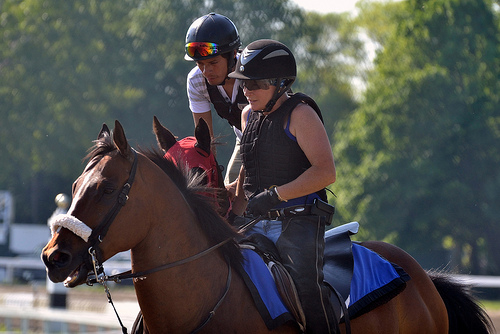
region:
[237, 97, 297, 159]
this is a woman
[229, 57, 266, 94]
this is a helmet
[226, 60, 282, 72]
the helmet is round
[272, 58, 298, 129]
the helmet is black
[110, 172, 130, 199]
this is a horse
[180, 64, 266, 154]
this is a man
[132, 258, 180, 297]
this is a strap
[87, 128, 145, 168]
this is an ear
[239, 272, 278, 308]
this is a blanket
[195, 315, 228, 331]
this is made of leather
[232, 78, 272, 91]
a pair of shades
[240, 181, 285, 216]
a pair of black gloves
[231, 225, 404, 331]
a blue saddle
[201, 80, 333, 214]
a black vest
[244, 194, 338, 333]
a pair of pants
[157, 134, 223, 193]
red mask on horse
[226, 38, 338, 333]
a lady jockey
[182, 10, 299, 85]
two helmets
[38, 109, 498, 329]
a brown horse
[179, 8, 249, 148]
a male rider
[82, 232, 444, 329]
the horse is brown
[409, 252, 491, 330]
the tail is black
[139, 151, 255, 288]
the mane is black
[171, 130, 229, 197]
the mask is red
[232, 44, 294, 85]
logo on the helmet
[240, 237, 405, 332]
blue blanket on horse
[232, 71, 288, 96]
the glasses on face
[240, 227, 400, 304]
saddle is on blanket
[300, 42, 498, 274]
the leaves on trees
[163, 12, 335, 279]
man behind the woman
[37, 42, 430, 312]
A lady on a horse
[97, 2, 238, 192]
A man on a horse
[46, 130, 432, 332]
Brown color horse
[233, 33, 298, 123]
Lady wearing black color helmet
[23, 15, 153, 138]
Trees behind the background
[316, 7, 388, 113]
Sky is seen between the branches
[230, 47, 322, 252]
Lady wearing a black gloves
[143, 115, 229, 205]
A red mask on the face of the horse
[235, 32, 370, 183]
The lady wearing black jacket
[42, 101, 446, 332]
Two horses standing together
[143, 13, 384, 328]
two people on horses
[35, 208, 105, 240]
white cloth on face of horse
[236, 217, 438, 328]
a white blanket on back of horse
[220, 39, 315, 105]
a black and gray helmet on head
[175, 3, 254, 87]
an all black helmet on head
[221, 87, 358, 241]
a black vest on girl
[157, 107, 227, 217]
a red cloth on horses head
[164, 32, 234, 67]
goggles on his helmet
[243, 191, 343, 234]
a black belt on girl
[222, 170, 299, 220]
black gloves on her hand